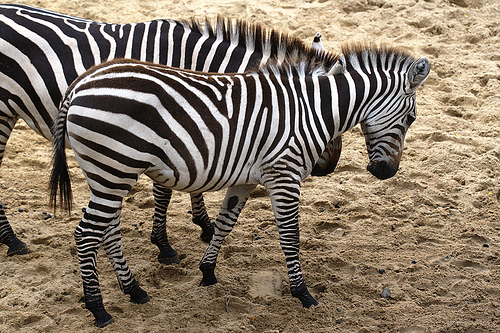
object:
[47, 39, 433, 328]
zebra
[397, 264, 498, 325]
ground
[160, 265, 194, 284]
print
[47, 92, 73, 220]
tail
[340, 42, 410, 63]
mane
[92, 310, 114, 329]
hoof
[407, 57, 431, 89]
ear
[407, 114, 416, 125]
eye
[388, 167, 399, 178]
nose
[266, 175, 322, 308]
leg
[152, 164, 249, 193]
stomach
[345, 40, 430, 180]
head